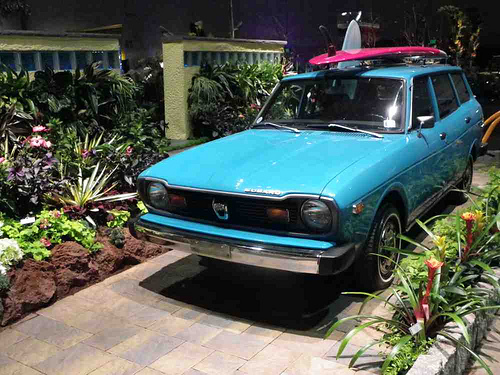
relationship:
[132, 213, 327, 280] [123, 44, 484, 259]
bumper on car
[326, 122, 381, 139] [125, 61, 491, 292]
wiper on car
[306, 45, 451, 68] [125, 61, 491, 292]
surfboard on car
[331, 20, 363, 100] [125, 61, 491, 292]
surfboard on car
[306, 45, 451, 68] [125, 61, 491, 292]
surfboard behind car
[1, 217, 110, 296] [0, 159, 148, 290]
rocks in front of plants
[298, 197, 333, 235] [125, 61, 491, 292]
headlight on car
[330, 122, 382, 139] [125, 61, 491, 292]
wiper of car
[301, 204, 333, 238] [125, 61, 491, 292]
headlight of car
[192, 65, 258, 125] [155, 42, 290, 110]
plants on wall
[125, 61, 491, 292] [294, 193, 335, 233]
car has light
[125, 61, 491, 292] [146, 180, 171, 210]
car has headlight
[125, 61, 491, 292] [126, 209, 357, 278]
car has bumper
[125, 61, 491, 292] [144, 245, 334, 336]
car has shadow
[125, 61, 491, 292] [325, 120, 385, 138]
car has wiper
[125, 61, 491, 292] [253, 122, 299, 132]
car has wiper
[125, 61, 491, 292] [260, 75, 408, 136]
car has windshield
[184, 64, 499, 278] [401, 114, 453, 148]
car has mirror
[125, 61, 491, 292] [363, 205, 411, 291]
car has wheel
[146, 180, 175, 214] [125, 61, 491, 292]
headlight of a car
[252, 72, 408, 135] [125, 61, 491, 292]
windshield of a car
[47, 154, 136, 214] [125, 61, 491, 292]
plant next to car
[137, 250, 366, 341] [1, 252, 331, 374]
shadow on ground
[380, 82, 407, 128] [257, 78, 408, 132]
light glare on windshield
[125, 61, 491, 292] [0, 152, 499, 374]
car sitting in ground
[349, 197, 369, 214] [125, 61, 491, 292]
side marker on car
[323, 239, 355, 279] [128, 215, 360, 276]
black cap on bumper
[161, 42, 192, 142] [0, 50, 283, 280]
wall behind plants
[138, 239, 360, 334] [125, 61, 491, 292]
shadow from a car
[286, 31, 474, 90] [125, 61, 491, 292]
surfboard on top of car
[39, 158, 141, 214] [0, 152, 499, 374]
plant are along side ground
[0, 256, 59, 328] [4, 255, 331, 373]
rocks are along side driveway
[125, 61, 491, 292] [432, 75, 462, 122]
car has windows